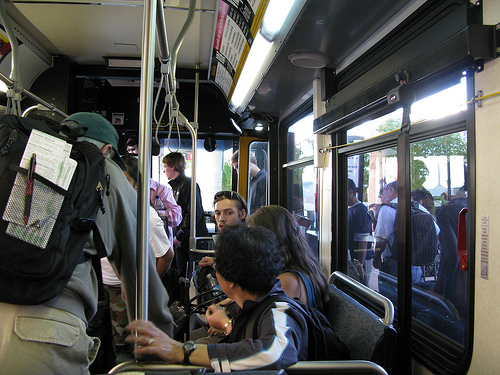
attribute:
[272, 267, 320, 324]
top — blue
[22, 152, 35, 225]
pen — red, black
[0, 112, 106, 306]
backpack — black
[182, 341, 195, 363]
watch — black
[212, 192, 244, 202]
sunglasses — here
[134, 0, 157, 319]
pole — silver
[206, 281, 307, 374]
jacket — striped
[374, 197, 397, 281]
shirt — white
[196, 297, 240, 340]
person — sitting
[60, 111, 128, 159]
hat — green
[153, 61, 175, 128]
strap — hanging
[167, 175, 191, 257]
jacket — black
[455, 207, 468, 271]
handle — red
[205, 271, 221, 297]
bottle — clear